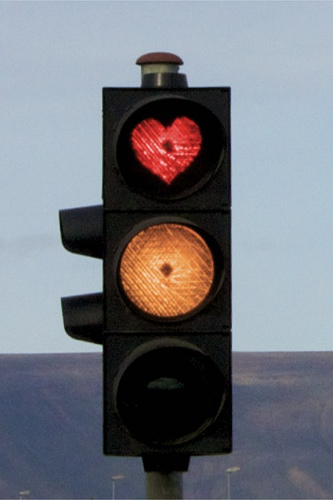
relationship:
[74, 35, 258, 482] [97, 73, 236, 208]
light has color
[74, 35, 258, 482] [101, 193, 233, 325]
light has color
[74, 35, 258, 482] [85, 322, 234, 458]
light has color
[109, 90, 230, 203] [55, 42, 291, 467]
color of light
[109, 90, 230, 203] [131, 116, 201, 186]
color  heart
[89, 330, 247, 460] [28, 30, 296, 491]
light of light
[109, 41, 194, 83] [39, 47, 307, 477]
top on light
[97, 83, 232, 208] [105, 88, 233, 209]
circle around light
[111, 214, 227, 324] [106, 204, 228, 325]
circle around light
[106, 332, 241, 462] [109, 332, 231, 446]
circle around light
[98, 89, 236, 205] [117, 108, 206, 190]
light shaped like heart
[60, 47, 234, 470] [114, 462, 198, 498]
light on post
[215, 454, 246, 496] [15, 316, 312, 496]
light in background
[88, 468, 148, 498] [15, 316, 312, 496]
light in background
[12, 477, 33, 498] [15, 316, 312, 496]
light in background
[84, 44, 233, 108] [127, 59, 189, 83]
top of post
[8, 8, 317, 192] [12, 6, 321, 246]
sky in background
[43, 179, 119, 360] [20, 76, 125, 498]
lights on left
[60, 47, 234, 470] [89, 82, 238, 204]
light with light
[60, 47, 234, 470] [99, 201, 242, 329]
light with light